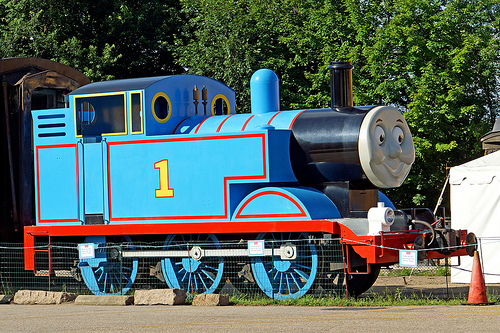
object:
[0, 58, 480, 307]
train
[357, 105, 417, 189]
face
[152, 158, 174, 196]
number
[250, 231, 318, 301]
wheels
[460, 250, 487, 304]
cone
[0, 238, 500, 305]
fence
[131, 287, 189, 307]
rocks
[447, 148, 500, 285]
building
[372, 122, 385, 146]
eyes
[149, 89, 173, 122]
windows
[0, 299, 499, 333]
road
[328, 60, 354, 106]
pipe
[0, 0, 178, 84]
trees